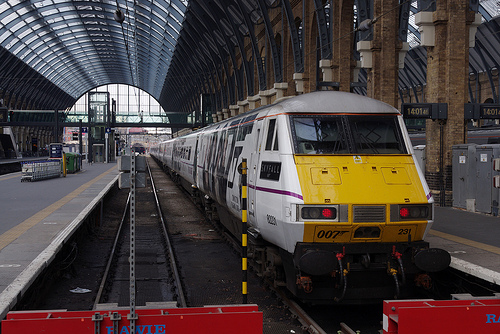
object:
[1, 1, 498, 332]
train station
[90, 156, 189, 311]
tracks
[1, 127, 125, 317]
terminal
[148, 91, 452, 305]
train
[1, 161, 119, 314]
platform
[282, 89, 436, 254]
front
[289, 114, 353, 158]
window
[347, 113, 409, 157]
window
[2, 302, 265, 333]
bumper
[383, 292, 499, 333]
bumper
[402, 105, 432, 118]
sign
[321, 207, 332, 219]
light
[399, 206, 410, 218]
light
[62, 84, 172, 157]
outside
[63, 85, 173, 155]
opening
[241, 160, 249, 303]
pole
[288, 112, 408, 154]
windshield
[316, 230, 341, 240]
007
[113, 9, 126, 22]
light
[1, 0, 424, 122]
ceiling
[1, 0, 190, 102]
middle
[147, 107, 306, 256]
side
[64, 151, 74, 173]
garbage bin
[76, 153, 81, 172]
garbage bin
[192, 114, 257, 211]
advertising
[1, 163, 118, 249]
stripe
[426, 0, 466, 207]
pillar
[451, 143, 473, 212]
electric box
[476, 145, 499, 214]
electric box